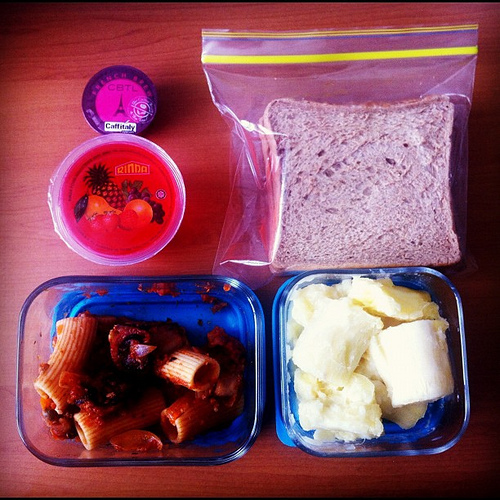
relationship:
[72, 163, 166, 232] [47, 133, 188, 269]
fruit in a bowl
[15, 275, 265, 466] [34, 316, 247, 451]
bowl of pasta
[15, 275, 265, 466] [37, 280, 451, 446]
bowl of food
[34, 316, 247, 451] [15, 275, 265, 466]
pasta in bowl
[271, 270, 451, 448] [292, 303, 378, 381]
bowl with cheese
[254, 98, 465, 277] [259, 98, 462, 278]
bag has a sandwich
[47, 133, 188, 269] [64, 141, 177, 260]
bowl of jello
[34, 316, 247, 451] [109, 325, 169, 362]
pasta has a sauce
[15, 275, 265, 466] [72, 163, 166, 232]
bowl of fruit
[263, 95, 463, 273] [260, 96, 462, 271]
slice of bread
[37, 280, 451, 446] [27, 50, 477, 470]
food all together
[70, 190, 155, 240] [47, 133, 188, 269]
pineapple in bowl